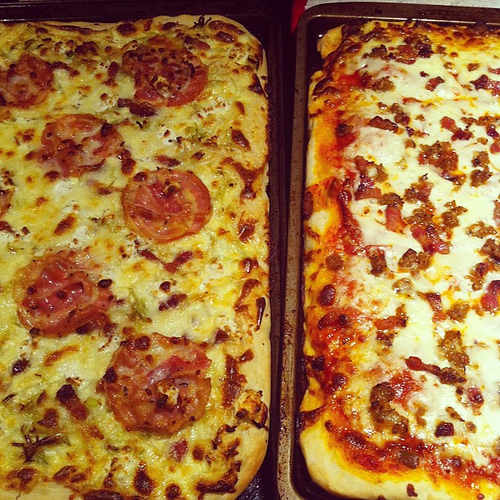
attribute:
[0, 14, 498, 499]
pizza — yellow